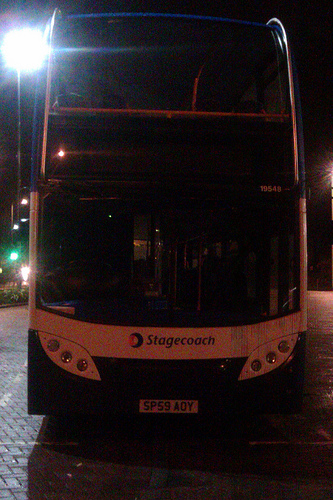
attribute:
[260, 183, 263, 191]
number — 1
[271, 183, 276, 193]
number — 4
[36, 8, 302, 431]
bus — double decker, big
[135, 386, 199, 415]
license plate — white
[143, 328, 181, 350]
stage — word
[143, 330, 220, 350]
word — written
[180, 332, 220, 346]
word — coach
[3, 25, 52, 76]
light — glowing, bright, smal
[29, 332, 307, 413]
paint — black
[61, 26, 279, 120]
window — main front, on front of the bus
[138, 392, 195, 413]
lettering — black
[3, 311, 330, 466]
ground — brick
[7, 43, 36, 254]
pole — metal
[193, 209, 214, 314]
pole — curved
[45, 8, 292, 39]
roof — blue